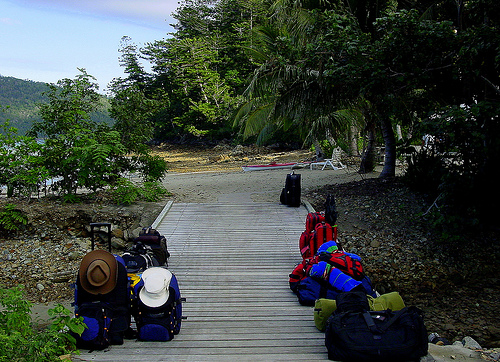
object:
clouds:
[1, 0, 184, 30]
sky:
[0, 1, 216, 95]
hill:
[0, 73, 117, 136]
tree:
[107, 1, 499, 185]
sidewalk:
[58, 198, 396, 361]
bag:
[130, 265, 182, 342]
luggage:
[289, 239, 373, 305]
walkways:
[36, 197, 382, 361]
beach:
[149, 166, 386, 201]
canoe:
[240, 159, 297, 175]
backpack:
[72, 257, 131, 353]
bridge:
[70, 199, 343, 362]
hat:
[77, 249, 121, 298]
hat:
[134, 265, 174, 309]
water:
[2, 138, 86, 154]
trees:
[0, 66, 175, 207]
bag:
[315, 303, 430, 361]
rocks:
[460, 333, 484, 351]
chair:
[310, 154, 350, 171]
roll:
[312, 290, 407, 330]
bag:
[298, 221, 340, 267]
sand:
[29, 161, 403, 199]